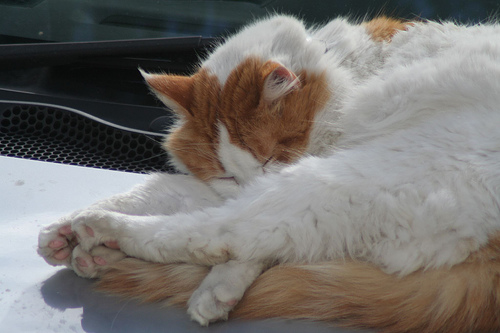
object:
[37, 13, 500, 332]
cat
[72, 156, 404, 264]
legs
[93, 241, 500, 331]
tail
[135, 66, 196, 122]
ear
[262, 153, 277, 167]
eye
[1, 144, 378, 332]
table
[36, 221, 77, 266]
paw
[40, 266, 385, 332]
shadow